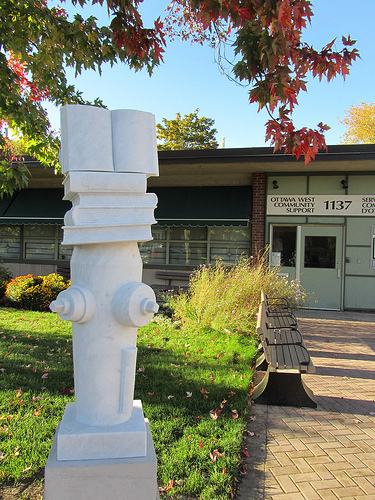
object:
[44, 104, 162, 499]
statue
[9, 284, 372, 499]
front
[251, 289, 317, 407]
benches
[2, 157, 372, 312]
center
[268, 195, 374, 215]
sign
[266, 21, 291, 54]
leaves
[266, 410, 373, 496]
pavers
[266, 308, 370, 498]
sidewalk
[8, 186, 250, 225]
awning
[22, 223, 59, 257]
windows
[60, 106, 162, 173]
book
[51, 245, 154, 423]
hydrant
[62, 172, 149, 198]
books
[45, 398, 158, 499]
base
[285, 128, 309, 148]
foliage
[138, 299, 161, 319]
knob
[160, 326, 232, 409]
grass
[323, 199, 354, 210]
1137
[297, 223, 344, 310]
door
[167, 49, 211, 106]
sky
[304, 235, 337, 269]
window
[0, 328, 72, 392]
shadow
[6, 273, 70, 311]
shrub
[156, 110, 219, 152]
tree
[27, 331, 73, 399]
leaves